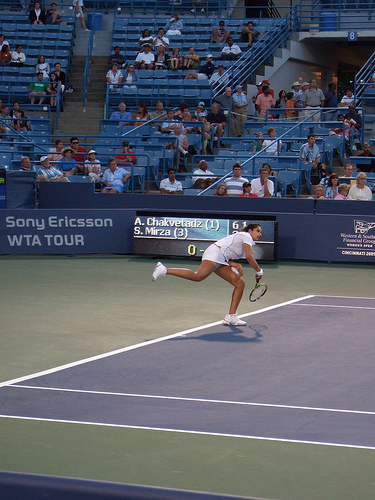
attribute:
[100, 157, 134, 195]
spectator — pictured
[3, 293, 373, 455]
surface — purple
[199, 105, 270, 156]
spectator — pictured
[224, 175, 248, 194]
shirt — striped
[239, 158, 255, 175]
seat — blue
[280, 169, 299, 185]
seat — blue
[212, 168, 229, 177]
seat — blue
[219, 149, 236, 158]
seat — blue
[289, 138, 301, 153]
seat — blue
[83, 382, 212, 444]
lines — white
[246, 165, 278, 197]
spectator — pictured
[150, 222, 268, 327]
woman — tennis-playing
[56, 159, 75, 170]
shirt — blue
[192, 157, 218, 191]
spectator — pictured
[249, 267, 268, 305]
tennis racket — green, yellow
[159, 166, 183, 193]
spectator — pictured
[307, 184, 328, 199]
spectator — pictured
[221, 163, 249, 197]
spectator — pictured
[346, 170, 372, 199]
spectator — pictured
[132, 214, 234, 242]
sign — score-displaying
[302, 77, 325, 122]
man — standing, match-watching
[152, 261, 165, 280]
shoes — white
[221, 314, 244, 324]
shoes — white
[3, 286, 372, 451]
tennis court — pictured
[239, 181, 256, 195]
spectator — pictured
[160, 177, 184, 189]
shirt — white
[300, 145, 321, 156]
shirt — blue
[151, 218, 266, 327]
tennis player — pictured